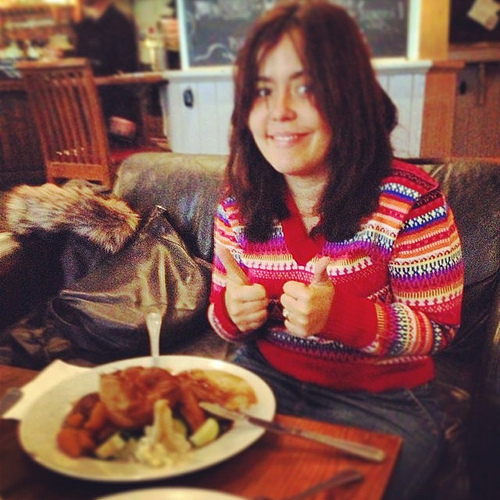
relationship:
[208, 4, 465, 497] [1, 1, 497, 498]
girl at a restaurant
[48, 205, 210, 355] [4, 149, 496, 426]
purse on a couch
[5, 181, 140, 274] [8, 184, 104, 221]
jacket with fur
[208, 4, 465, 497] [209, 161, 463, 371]
girl wearing a sweater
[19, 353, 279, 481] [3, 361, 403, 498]
dinner on table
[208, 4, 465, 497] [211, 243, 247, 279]
girl has thumb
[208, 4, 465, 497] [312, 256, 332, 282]
girl has thumb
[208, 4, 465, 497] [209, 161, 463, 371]
girl has a sweater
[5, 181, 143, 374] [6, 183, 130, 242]
jacket with fur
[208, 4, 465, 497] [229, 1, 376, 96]
girl has hair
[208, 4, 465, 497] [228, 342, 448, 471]
girl wearing jeans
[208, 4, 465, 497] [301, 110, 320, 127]
girl has skin